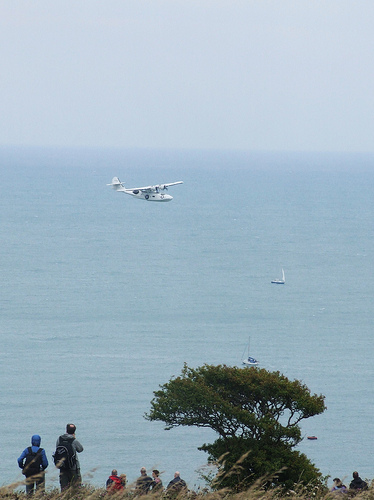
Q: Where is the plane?
A: Midair.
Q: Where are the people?
A: Cliff.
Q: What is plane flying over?
A: Ocean.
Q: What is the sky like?
A: Hazy.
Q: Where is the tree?
A: On edge.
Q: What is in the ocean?
A: Boat.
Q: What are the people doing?
A: Watching.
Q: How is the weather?
A: Fair.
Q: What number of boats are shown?
A: 2.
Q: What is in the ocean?
A: Sailboat.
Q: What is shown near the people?
A: Tree.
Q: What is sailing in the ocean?
A: Boat.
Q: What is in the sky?
A: Plane.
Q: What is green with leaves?
A: Tree.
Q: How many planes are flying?
A: One.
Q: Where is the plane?
A: In the sky.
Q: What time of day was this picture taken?
A: Daytime.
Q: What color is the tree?
A: Green.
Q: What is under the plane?
A: Water.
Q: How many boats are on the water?
A: Two.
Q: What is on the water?
A: Boats.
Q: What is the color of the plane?
A: White.